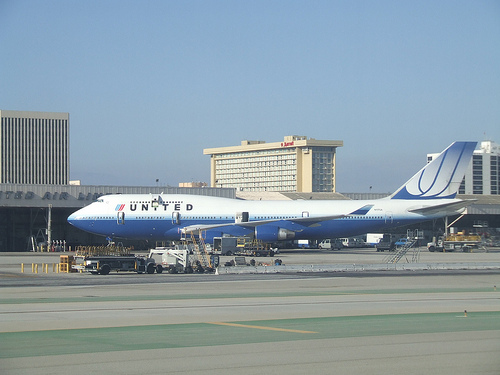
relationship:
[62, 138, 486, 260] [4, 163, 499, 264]
airline at airport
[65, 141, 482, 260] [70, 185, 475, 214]
airline blue white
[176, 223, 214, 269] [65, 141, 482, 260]
stairs by airline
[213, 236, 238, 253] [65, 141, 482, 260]
luggage by airline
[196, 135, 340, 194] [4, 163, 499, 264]
building behind airport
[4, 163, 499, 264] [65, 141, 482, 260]
airport behind airline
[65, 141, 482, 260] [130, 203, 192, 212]
airline belongs name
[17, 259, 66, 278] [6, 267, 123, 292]
poles marking parking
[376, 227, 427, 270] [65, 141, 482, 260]
stair at airline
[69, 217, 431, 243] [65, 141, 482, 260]
blue white airline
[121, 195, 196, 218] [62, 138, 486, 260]
name of airline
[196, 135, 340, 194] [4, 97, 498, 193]
building in background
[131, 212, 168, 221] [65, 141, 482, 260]
windows on airline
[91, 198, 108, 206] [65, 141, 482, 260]
window of airline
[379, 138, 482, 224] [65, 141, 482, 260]
tail of airline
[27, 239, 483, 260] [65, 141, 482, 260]
road for airline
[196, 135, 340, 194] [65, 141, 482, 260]
building near airline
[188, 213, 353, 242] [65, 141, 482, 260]
wing of airline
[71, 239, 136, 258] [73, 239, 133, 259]
cones or barriers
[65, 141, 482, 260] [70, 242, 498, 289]
airline on tarmac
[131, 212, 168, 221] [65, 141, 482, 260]
windows of airline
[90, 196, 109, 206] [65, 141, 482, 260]
cockpit of airline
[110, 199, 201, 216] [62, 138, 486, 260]
logo for airline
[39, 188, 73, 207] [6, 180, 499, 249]
word on building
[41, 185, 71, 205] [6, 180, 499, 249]
air on building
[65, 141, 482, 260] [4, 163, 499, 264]
airline by airport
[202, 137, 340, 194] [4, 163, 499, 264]
building by airport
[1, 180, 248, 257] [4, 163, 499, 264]
terminal in airport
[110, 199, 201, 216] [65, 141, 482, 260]
logo on airline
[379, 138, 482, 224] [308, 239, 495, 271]
tail on runway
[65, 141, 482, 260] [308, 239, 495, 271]
airline on runway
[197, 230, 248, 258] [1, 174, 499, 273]
luggage by airport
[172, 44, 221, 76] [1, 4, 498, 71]
blue cloudless sky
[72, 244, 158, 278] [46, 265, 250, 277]
cart on concrete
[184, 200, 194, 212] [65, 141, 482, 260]
text on airline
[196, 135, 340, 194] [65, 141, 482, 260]
building behind airline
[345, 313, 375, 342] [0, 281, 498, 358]
paint on ground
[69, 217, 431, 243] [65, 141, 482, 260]
blue on airline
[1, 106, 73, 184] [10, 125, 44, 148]
building with windows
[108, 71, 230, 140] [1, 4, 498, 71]
bright blue sky